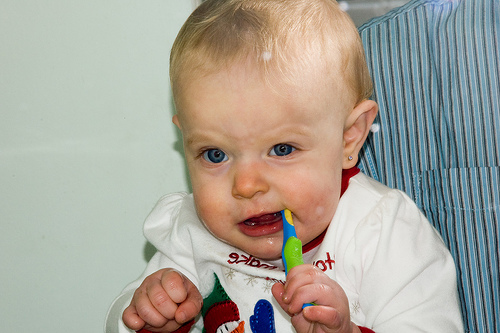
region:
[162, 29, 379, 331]
baby brushing her teeth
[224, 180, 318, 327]
baby holding a toothbrush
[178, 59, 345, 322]
baby holding a toothbrush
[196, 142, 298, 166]
Two eyes are blue.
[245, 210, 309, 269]
A blue, yellow and green object is in the mouth.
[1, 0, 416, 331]
A wall is white.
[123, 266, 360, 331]
Two hands with fingers curled.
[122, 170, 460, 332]
A baby is wearing a mostly white smock.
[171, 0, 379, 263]
A baby has blonde hair.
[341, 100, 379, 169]
An ear is pierced.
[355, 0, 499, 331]
A cover has blue stripes.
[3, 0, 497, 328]
A baby is holding a toothbrush in his mouth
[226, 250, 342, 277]
Red writing is on a white cloth.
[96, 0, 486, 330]
this is a child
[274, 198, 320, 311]
the child has a toothbrush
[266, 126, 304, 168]
the eye of a child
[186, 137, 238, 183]
the eye of a child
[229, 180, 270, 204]
the nose of a child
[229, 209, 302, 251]
the mouth of a child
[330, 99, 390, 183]
the ear of a child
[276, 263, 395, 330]
the hand of a child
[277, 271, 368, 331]
the hand of a child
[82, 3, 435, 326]
A baby brushing its teeth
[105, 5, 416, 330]
A baby brushing its teeth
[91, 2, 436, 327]
A baby brushing its teeth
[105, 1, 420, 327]
A baby brushing its teeth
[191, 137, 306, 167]
baby blue eyes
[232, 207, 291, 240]
baby's open mouth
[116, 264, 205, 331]
baby's closed right hand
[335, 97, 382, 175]
baby's left ear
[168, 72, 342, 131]
baby's white forehead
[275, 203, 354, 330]
toy in baby's left hand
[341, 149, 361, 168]
ear ring in baby's left ear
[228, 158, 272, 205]
baby nose and two nostrils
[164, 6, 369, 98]
light brown hair on baby's head